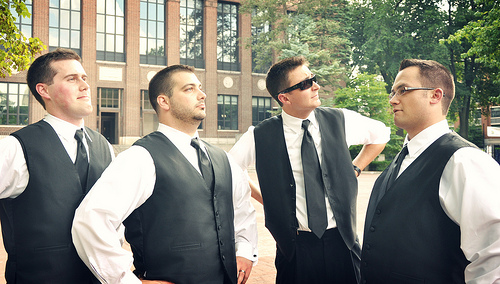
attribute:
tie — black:
[287, 119, 352, 234]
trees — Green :
[213, 0, 499, 173]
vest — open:
[273, 121, 369, 251]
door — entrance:
[98, 107, 120, 143]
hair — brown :
[27, 50, 81, 107]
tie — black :
[299, 119, 334, 236]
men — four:
[1, 45, 498, 277]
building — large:
[2, 2, 352, 163]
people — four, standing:
[2, 47, 498, 282]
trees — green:
[240, 1, 493, 62]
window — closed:
[48, 3, 88, 60]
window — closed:
[90, 0, 132, 66]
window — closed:
[138, 0, 172, 67]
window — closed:
[181, 1, 209, 73]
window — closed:
[216, 0, 245, 75]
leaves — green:
[237, 0, 499, 170]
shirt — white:
[397, 117, 482, 282]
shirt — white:
[225, 103, 392, 233]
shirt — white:
[67, 122, 259, 281]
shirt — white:
[2, 114, 114, 199]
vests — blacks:
[9, 117, 462, 252]